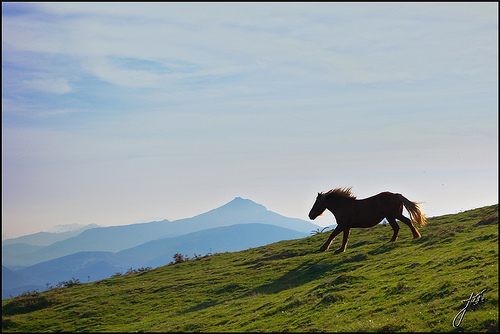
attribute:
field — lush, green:
[4, 197, 495, 333]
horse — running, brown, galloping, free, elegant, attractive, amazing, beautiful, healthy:
[307, 184, 422, 256]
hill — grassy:
[3, 198, 497, 333]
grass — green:
[6, 197, 499, 334]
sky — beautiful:
[2, 1, 499, 229]